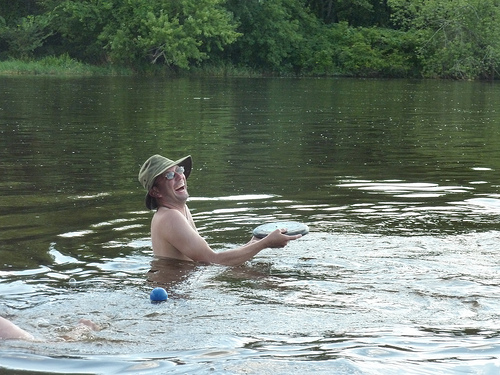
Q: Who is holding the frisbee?
A: The man.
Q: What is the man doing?
A: Laughing.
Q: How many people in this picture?
A: Two.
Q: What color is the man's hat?
A: Olive green.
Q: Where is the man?
A: In the water.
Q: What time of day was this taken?
A: Day time.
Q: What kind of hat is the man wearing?
A: A bucket hat.